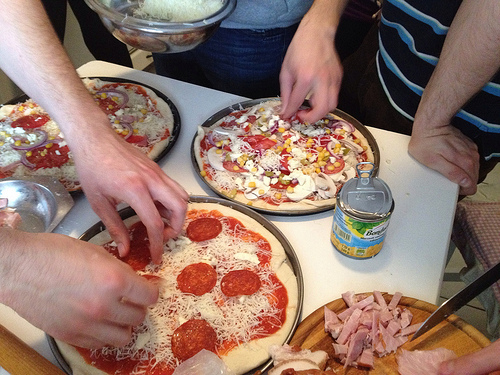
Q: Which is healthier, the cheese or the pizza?
A: The cheese is healthier than the pizza.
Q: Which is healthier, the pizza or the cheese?
A: The cheese is healthier than the pizza.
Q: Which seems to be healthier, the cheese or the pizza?
A: The cheese is healthier than the pizza.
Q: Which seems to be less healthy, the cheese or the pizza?
A: The pizza is less healthy than the cheese.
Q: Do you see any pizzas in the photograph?
A: Yes, there is a pizza.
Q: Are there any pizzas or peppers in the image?
A: Yes, there is a pizza.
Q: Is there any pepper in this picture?
A: No, there are no peppers.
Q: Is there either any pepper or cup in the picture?
A: No, there are no peppers or cups.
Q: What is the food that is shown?
A: The food is a pizza.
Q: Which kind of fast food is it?
A: The food is a pizza.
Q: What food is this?
A: This is a pizza.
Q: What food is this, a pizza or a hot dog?
A: This is a pizza.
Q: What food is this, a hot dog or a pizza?
A: This is a pizza.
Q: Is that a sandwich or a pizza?
A: That is a pizza.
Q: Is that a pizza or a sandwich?
A: That is a pizza.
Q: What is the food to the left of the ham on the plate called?
A: The food is a pizza.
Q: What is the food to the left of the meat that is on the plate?
A: The food is a pizza.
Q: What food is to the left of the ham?
A: The food is a pizza.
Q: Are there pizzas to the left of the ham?
A: Yes, there is a pizza to the left of the ham.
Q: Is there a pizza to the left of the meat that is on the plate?
A: Yes, there is a pizza to the left of the ham.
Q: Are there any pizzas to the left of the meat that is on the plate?
A: Yes, there is a pizza to the left of the ham.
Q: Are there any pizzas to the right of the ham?
A: No, the pizza is to the left of the ham.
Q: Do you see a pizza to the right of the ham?
A: No, the pizza is to the left of the ham.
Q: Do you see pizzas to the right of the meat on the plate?
A: No, the pizza is to the left of the ham.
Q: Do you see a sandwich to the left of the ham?
A: No, there is a pizza to the left of the ham.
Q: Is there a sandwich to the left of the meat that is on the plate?
A: No, there is a pizza to the left of the ham.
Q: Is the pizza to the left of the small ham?
A: Yes, the pizza is to the left of the ham.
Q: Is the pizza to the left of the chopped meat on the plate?
A: Yes, the pizza is to the left of the ham.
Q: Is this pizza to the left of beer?
A: No, the pizza is to the left of the ham.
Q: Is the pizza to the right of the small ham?
A: No, the pizza is to the left of the ham.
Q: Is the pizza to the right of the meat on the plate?
A: No, the pizza is to the left of the ham.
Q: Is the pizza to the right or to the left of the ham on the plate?
A: The pizza is to the left of the ham.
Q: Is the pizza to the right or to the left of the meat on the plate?
A: The pizza is to the left of the ham.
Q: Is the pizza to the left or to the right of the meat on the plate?
A: The pizza is to the left of the ham.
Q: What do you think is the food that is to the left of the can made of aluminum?
A: The food is a pizza.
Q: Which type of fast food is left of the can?
A: The food is a pizza.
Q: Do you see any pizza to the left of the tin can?
A: Yes, there is a pizza to the left of the can.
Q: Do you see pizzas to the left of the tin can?
A: Yes, there is a pizza to the left of the can.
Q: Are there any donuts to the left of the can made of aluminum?
A: No, there is a pizza to the left of the can.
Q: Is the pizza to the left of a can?
A: Yes, the pizza is to the left of a can.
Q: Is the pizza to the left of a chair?
A: No, the pizza is to the left of a can.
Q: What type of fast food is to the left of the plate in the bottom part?
A: The food is a pizza.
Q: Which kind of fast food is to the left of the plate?
A: The food is a pizza.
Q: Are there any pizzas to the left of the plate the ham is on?
A: Yes, there is a pizza to the left of the plate.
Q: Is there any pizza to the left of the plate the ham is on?
A: Yes, there is a pizza to the left of the plate.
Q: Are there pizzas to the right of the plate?
A: No, the pizza is to the left of the plate.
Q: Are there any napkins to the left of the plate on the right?
A: No, there is a pizza to the left of the plate.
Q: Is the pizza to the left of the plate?
A: Yes, the pizza is to the left of the plate.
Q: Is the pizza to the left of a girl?
A: No, the pizza is to the left of the plate.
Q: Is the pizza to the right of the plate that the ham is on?
A: No, the pizza is to the left of the plate.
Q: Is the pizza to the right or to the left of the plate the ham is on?
A: The pizza is to the left of the plate.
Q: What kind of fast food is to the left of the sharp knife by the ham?
A: The food is a pizza.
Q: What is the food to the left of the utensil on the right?
A: The food is a pizza.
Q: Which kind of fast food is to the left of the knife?
A: The food is a pizza.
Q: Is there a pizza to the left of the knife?
A: Yes, there is a pizza to the left of the knife.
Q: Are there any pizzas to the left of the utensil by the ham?
A: Yes, there is a pizza to the left of the knife.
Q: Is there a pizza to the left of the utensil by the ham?
A: Yes, there is a pizza to the left of the knife.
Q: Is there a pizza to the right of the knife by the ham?
A: No, the pizza is to the left of the knife.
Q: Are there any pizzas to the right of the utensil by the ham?
A: No, the pizza is to the left of the knife.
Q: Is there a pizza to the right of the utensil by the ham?
A: No, the pizza is to the left of the knife.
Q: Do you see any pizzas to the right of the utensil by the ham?
A: No, the pizza is to the left of the knife.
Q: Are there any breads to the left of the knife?
A: No, there is a pizza to the left of the knife.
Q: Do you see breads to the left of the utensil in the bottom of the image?
A: No, there is a pizza to the left of the knife.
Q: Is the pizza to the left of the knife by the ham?
A: Yes, the pizza is to the left of the knife.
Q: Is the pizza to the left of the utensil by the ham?
A: Yes, the pizza is to the left of the knife.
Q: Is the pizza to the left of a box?
A: No, the pizza is to the left of the knife.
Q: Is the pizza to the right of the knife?
A: No, the pizza is to the left of the knife.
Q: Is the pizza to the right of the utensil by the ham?
A: No, the pizza is to the left of the knife.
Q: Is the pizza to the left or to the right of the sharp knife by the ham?
A: The pizza is to the left of the knife.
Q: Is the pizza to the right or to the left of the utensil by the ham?
A: The pizza is to the left of the knife.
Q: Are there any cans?
A: Yes, there is a can.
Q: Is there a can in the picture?
A: Yes, there is a can.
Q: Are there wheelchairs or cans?
A: Yes, there is a can.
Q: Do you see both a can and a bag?
A: No, there is a can but no bags.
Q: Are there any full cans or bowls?
A: Yes, there is a full can.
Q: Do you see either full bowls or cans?
A: Yes, there is a full can.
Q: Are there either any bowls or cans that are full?
A: Yes, the can is full.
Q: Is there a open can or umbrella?
A: Yes, there is an open can.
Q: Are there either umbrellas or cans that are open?
A: Yes, the can is open.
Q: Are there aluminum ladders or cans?
A: Yes, there is an aluminum can.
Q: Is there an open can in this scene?
A: Yes, there is an open can.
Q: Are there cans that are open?
A: Yes, there is a can that is open.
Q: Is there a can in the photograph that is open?
A: Yes, there is a can that is open.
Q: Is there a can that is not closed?
A: Yes, there is a open can.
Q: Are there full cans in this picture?
A: Yes, there is a full can.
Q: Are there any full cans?
A: Yes, there is a full can.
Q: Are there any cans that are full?
A: Yes, there is a can that is full.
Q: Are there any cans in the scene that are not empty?
A: Yes, there is an full can.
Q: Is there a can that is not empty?
A: Yes, there is an full can.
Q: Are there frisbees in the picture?
A: No, there are no frisbees.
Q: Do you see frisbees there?
A: No, there are no frisbees.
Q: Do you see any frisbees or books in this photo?
A: No, there are no frisbees or books.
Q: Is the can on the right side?
A: Yes, the can is on the right of the image.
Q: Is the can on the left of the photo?
A: No, the can is on the right of the image.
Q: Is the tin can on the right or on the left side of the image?
A: The can is on the right of the image.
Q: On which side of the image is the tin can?
A: The can is on the right of the image.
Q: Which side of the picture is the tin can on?
A: The can is on the right of the image.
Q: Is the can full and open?
A: Yes, the can is full and open.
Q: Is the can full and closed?
A: No, the can is full but open.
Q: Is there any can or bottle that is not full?
A: No, there is a can but it is full.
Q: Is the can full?
A: Yes, the can is full.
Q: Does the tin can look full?
A: Yes, the can is full.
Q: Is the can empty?
A: No, the can is full.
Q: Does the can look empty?
A: No, the can is full.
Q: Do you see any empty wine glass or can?
A: No, there is a can but it is full.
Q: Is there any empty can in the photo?
A: No, there is a can but it is full.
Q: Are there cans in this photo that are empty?
A: No, there is a can but it is full.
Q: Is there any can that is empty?
A: No, there is a can but it is full.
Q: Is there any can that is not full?
A: No, there is a can but it is full.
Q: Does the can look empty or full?
A: The can is full.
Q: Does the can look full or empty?
A: The can is full.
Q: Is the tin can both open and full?
A: Yes, the can is open and full.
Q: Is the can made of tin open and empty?
A: No, the can is open but full.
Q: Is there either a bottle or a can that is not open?
A: No, there is a can but it is open.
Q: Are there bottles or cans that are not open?
A: No, there is a can but it is open.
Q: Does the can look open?
A: Yes, the can is open.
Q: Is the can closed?
A: No, the can is open.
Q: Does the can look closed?
A: No, the can is open.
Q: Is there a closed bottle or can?
A: No, there is a can but it is open.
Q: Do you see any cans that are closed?
A: No, there is a can but it is open.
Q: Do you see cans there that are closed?
A: No, there is a can but it is open.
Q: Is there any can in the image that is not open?
A: No, there is a can but it is open.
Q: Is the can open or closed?
A: The can is open.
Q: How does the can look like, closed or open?
A: The can is open.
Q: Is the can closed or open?
A: The can is open.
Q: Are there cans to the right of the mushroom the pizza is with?
A: Yes, there is a can to the right of the mushroom.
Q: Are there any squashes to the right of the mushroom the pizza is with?
A: No, there is a can to the right of the mushroom.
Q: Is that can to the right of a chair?
A: No, the can is to the right of the mushroom.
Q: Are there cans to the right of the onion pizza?
A: Yes, there is a can to the right of the pizza.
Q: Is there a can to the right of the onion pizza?
A: Yes, there is a can to the right of the pizza.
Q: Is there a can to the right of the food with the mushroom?
A: Yes, there is a can to the right of the pizza.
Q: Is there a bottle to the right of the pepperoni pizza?
A: No, there is a can to the right of the pizza.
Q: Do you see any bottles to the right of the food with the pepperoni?
A: No, there is a can to the right of the pizza.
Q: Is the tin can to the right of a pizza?
A: Yes, the can is to the right of a pizza.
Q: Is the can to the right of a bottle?
A: No, the can is to the right of a pizza.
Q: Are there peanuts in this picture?
A: No, there are no peanuts.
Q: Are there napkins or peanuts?
A: No, there are no peanuts or napkins.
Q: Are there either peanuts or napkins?
A: No, there are no peanuts or napkins.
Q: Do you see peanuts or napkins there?
A: No, there are no peanuts or napkins.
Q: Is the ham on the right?
A: Yes, the ham is on the right of the image.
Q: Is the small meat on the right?
A: Yes, the ham is on the right of the image.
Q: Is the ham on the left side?
A: No, the ham is on the right of the image.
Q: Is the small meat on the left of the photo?
A: No, the ham is on the right of the image.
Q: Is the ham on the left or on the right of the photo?
A: The ham is on the right of the image.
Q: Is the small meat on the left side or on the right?
A: The ham is on the right of the image.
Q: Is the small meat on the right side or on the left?
A: The ham is on the right of the image.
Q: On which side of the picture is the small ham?
A: The ham is on the right of the image.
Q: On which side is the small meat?
A: The ham is on the right of the image.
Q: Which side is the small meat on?
A: The ham is on the right of the image.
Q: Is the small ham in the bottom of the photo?
A: Yes, the ham is in the bottom of the image.